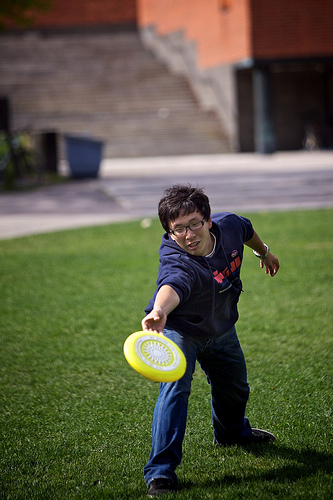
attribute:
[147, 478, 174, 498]
shoes — black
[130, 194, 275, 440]
person — playing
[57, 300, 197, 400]
frisbee — yellow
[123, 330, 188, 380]
frisbee — yellow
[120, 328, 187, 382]
circle — round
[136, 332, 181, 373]
design — white